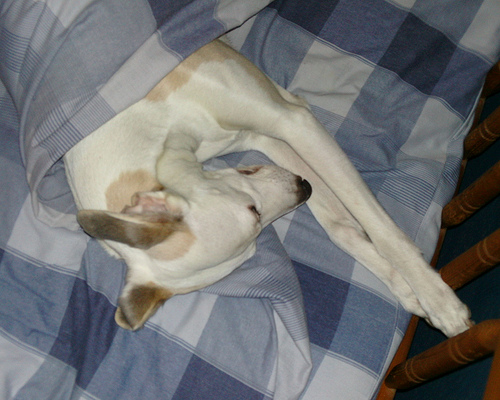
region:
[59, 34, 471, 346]
An animal on a bed.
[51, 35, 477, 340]
A dog on a bed.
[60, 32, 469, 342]
A dog sleeping on a bed.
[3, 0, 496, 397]
Blue and white plaid sheets.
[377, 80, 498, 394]
A brown wooden railing.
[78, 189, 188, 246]
The ear of a dog.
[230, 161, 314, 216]
The snout of a dog.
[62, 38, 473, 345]
A brown and white dog sleeping.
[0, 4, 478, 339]
Dog wrapped in a bed sheet.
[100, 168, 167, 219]
Brown spot on a dog.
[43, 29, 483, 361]
the dog is brown and white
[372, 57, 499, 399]
the bed's headboard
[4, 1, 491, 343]
a dog is lying in the bed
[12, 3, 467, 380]
the dog is under the sheet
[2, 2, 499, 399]
the sheets are checkered blue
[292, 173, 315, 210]
the dog has a black nose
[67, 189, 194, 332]
the dogs ears are brown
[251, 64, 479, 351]
the dogs front legs are white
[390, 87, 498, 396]
the carpet is blue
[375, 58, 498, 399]
the headboard is wooden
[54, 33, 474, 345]
white and tan dog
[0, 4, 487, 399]
white and blue plaid blanket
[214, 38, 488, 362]
dog's white outstretched legs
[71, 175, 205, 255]
dog's light brown ear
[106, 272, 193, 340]
dog's light brown ear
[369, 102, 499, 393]
brown wooden foot board rungs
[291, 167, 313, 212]
dog's wet black nose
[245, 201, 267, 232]
dog's left eye ball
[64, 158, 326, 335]
dog's white and tan head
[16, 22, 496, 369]
dog laying in a bed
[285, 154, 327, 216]
nose of the dog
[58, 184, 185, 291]
ear of the dog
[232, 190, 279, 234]
eye of the dog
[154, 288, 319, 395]
blue and white sheet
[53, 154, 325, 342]
white and brown dog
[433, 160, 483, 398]
wooden objects next to dog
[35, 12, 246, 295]
cover on the dog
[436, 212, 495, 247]
blue ground in photo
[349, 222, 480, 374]
legs of the dog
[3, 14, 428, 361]
one dog laying down